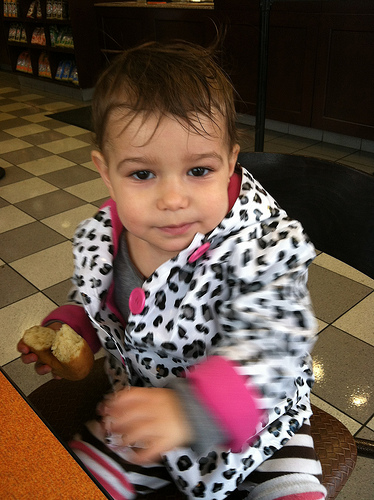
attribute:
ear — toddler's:
[81, 150, 113, 190]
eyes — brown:
[115, 153, 235, 197]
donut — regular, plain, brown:
[18, 322, 92, 379]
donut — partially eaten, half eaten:
[20, 322, 92, 384]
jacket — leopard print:
[100, 221, 344, 381]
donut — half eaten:
[15, 319, 99, 380]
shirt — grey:
[111, 236, 145, 324]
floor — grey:
[1, 74, 371, 496]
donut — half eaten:
[22, 313, 97, 394]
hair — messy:
[85, 36, 223, 150]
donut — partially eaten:
[5, 301, 142, 394]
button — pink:
[124, 283, 149, 317]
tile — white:
[27, 159, 56, 180]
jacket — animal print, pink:
[49, 217, 314, 407]